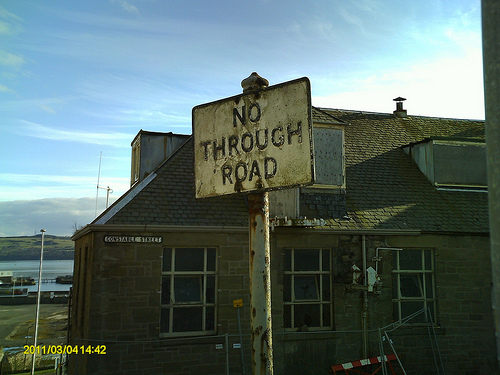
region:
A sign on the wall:
[98, 229, 167, 250]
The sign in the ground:
[192, 60, 329, 372]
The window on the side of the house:
[150, 243, 225, 348]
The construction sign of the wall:
[323, 348, 410, 373]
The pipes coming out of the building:
[343, 236, 383, 363]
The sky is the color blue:
[34, 11, 444, 61]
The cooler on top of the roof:
[393, 123, 490, 208]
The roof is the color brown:
[348, 115, 422, 227]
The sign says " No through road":
[198, 99, 307, 187]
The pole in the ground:
[243, 200, 280, 372]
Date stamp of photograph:
[21, 342, 78, 358]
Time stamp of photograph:
[79, 340, 108, 358]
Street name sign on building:
[100, 232, 163, 245]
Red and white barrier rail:
[326, 346, 393, 371]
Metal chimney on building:
[386, 94, 408, 119]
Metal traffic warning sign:
[185, 69, 315, 370]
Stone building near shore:
[64, 74, 492, 373]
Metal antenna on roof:
[85, 147, 117, 217]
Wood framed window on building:
[155, 241, 217, 336]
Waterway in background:
[0, 259, 77, 296]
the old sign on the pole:
[207, 86, 295, 370]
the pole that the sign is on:
[230, 78, 282, 365]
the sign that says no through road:
[177, 101, 337, 201]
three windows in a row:
[162, 238, 439, 344]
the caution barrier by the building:
[329, 344, 410, 369]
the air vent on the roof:
[385, 90, 418, 131]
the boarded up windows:
[304, 120, 486, 200]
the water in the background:
[4, 261, 76, 293]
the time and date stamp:
[17, 338, 110, 360]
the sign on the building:
[98, 233, 175, 248]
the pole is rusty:
[245, 194, 284, 356]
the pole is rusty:
[225, 179, 279, 373]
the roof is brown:
[312, 110, 382, 211]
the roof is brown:
[357, 190, 403, 227]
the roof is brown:
[116, 172, 201, 233]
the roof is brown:
[325, 105, 397, 174]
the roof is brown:
[331, 174, 488, 263]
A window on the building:
[162, 241, 216, 332]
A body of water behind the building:
[1, 258, 73, 290]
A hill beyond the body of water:
[3, 232, 74, 257]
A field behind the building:
[0, 302, 70, 343]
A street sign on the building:
[102, 235, 163, 244]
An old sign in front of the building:
[187, 77, 318, 372]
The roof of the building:
[87, 107, 492, 228]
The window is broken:
[390, 240, 435, 315]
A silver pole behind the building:
[25, 230, 45, 371]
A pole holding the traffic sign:
[246, 188, 278, 373]